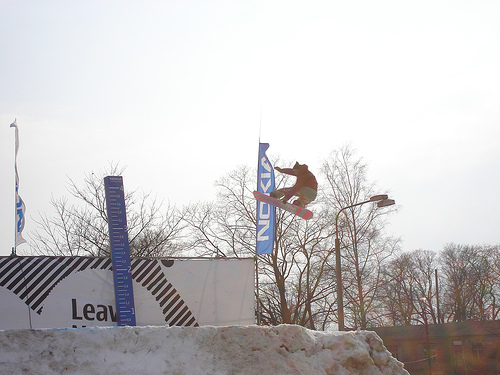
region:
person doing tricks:
[251, 146, 322, 224]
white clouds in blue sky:
[10, 21, 47, 62]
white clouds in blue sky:
[59, 23, 104, 74]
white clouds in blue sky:
[399, 93, 422, 124]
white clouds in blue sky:
[432, 138, 482, 231]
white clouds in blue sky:
[131, 63, 170, 104]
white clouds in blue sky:
[259, 35, 318, 111]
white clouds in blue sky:
[188, 63, 231, 123]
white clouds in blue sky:
[80, 111, 144, 164]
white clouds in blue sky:
[184, 24, 238, 105]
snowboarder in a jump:
[253, 154, 321, 218]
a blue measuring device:
[103, 176, 135, 328]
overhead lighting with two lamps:
[332, 193, 401, 340]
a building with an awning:
[375, 321, 499, 372]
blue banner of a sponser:
[252, 134, 275, 311]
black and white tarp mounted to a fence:
[1, 252, 256, 332]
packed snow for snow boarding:
[1, 321, 403, 373]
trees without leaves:
[43, 157, 498, 325]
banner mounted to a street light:
[5, 116, 31, 261]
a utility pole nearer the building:
[432, 266, 443, 354]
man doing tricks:
[255, 155, 322, 218]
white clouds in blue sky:
[29, 33, 109, 117]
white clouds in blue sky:
[229, 45, 287, 102]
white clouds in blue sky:
[371, 81, 426, 135]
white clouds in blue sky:
[107, 32, 162, 74]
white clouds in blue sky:
[136, 92, 216, 146]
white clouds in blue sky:
[34, 135, 74, 165]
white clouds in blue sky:
[40, 43, 105, 93]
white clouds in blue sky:
[401, 136, 453, 168]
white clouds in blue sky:
[273, 58, 325, 105]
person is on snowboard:
[241, 137, 333, 245]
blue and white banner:
[248, 144, 288, 262]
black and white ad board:
[8, 248, 233, 342]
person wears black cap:
[272, 153, 294, 175]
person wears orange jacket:
[274, 157, 316, 197]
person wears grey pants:
[274, 185, 315, 206]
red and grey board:
[257, 191, 317, 223]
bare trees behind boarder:
[87, 171, 479, 326]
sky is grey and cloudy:
[257, 23, 457, 121]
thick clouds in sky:
[228, 48, 378, 156]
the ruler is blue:
[95, 168, 157, 336]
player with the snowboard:
[241, 149, 348, 240]